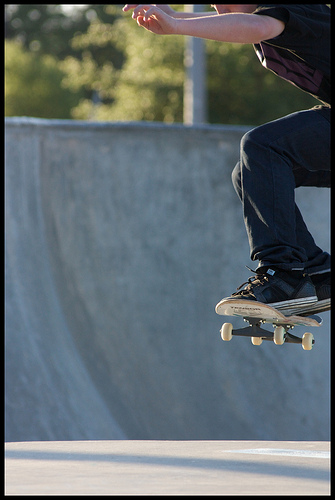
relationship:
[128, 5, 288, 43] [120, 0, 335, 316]
arm on boy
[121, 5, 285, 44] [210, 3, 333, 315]
arm of skateboarder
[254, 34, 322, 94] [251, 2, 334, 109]
logo of tee shirt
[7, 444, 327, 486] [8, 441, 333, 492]
shadow on pavement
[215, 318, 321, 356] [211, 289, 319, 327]
wheels on skateboard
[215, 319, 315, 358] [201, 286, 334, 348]
wheels on skateboard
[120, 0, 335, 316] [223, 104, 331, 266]
boy with jeans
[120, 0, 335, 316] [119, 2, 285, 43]
boy with arm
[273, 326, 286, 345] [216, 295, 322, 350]
wheels on skateboard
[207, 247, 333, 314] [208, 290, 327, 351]
feet on skateboard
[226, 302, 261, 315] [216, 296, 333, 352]
black logo on  bottom of skateboard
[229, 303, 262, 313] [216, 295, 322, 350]
writing on skateboard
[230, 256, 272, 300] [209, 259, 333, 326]
shoe strings on shoe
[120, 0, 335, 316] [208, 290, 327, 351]
boy doing trick on skateboard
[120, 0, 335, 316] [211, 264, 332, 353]
boy wearing black sneakers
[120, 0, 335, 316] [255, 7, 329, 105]
boy wearing tee shirt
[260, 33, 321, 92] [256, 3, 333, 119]
logo on tee shirt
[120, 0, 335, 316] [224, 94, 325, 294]
boy wearing jeans